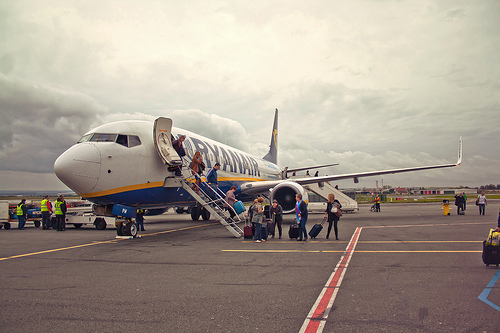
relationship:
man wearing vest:
[38, 194, 51, 229] [40, 197, 47, 211]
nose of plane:
[53, 142, 101, 195] [52, 107, 466, 241]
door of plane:
[152, 116, 180, 166] [52, 107, 466, 241]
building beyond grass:
[409, 188, 478, 197] [357, 194, 498, 203]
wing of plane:
[233, 135, 463, 196] [52, 107, 466, 241]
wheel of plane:
[124, 223, 138, 236] [52, 107, 466, 241]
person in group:
[324, 192, 341, 240] [245, 195, 343, 243]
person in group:
[268, 198, 284, 240] [245, 195, 343, 243]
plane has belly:
[52, 107, 466, 241] [96, 193, 266, 205]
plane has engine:
[52, 107, 466, 241] [268, 181, 308, 218]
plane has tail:
[52, 107, 466, 241] [260, 107, 281, 164]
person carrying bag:
[294, 193, 309, 241] [289, 218, 302, 241]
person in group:
[294, 193, 309, 241] [245, 195, 343, 243]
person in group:
[251, 197, 264, 244] [245, 195, 343, 243]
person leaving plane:
[222, 185, 237, 217] [52, 107, 466, 241]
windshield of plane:
[77, 130, 143, 148] [52, 107, 466, 241]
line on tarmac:
[299, 226, 363, 331] [2, 203, 495, 332]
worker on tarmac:
[14, 198, 28, 229] [2, 203, 495, 332]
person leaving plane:
[206, 161, 221, 203] [52, 107, 466, 241]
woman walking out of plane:
[189, 148, 203, 196] [52, 107, 466, 241]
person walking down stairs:
[222, 185, 237, 217] [176, 164, 243, 242]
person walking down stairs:
[206, 161, 221, 203] [176, 164, 243, 242]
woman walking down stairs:
[189, 148, 203, 196] [176, 164, 243, 242]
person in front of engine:
[294, 193, 309, 241] [268, 181, 308, 218]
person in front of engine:
[324, 192, 341, 240] [268, 181, 308, 218]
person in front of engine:
[268, 198, 284, 240] [268, 181, 308, 218]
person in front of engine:
[251, 197, 264, 244] [268, 181, 308, 218]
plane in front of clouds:
[52, 107, 466, 241] [0, 3, 496, 190]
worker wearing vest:
[53, 196, 67, 229] [55, 201, 63, 215]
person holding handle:
[324, 192, 341, 240] [319, 215, 327, 228]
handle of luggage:
[319, 215, 327, 228] [308, 217, 328, 240]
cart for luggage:
[0, 197, 42, 229] [26, 206, 41, 217]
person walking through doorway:
[172, 134, 187, 158] [169, 130, 187, 170]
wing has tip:
[233, 135, 463, 196] [455, 130, 465, 166]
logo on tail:
[272, 126, 280, 149] [260, 107, 281, 164]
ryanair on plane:
[190, 136, 262, 179] [52, 107, 466, 241]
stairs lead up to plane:
[176, 164, 243, 242] [52, 107, 466, 241]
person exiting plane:
[172, 134, 187, 158] [52, 107, 466, 241]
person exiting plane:
[206, 161, 221, 203] [52, 107, 466, 241]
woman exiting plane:
[189, 148, 203, 196] [52, 107, 466, 241]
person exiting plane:
[222, 185, 237, 217] [52, 107, 466, 241]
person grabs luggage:
[268, 198, 284, 240] [266, 218, 274, 236]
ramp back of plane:
[287, 173, 359, 211] [52, 107, 466, 241]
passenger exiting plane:
[314, 169, 321, 178] [52, 107, 466, 241]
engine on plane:
[268, 181, 308, 218] [52, 107, 466, 241]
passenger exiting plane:
[291, 171, 298, 178] [52, 107, 466, 241]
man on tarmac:
[473, 189, 489, 216] [2, 203, 495, 332]